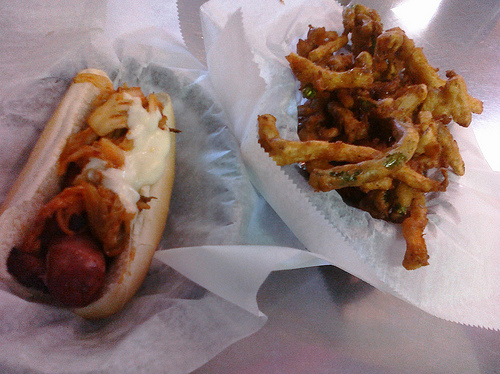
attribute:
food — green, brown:
[287, 19, 454, 200]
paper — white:
[282, 185, 330, 250]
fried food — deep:
[315, 34, 424, 183]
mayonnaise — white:
[138, 133, 158, 190]